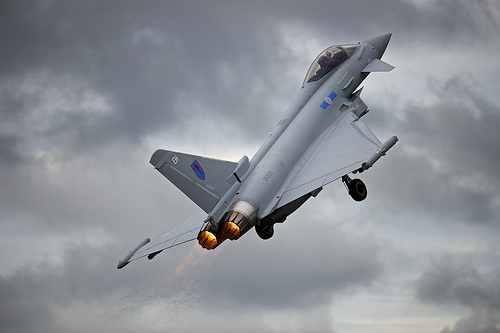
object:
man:
[318, 52, 337, 70]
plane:
[116, 32, 399, 269]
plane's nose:
[358, 32, 393, 56]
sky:
[0, 1, 498, 331]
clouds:
[51, 31, 148, 95]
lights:
[196, 221, 238, 251]